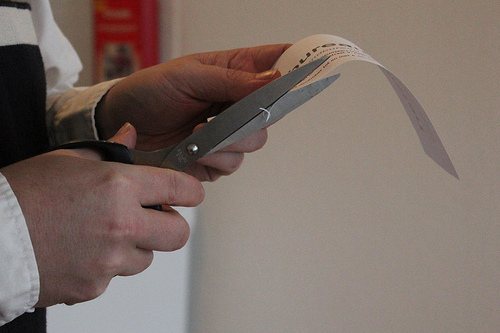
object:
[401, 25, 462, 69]
color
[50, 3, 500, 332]
walls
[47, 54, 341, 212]
scissors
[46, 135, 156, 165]
handle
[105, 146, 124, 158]
black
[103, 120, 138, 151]
thumb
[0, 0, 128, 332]
shirt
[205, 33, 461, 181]
paper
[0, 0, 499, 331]
picture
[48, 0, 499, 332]
indoors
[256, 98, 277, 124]
sliver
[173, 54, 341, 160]
two blades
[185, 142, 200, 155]
screw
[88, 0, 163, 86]
blury red object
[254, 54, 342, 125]
cut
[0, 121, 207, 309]
hand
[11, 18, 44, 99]
black and white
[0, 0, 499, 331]
background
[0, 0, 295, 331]
man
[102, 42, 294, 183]
hands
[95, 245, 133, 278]
knuckles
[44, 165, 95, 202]
caucasian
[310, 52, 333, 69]
tip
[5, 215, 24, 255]
white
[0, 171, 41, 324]
cuff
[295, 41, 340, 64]
black text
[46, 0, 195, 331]
wall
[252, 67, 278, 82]
fingernails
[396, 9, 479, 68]
beige